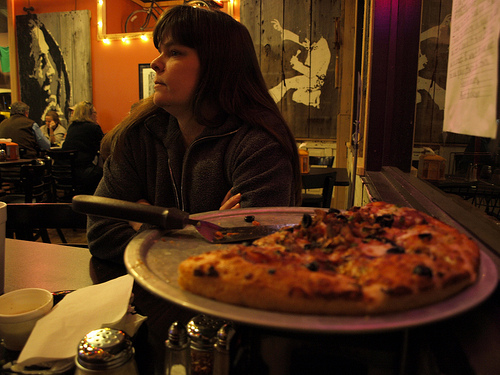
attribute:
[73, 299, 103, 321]
paper — white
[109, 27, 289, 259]
lady — brunette, caucasian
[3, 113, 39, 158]
vest — gray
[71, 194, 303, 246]
pie server — metal, black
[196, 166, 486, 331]
pizza — fat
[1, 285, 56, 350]
cup — white, styrofoam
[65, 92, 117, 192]
woman — blonde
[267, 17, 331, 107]
elvis drawing — white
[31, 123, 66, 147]
jacket — white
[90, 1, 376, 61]
lights — fluorescent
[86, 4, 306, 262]
woman — patron, caucasian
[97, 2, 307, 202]
hair — black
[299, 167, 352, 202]
table — black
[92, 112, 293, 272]
coat — black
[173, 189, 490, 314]
pizza — big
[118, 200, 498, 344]
platter — metal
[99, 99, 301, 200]
jacket — black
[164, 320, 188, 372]
salt shaker — silver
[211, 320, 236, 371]
pepper shaker — silver